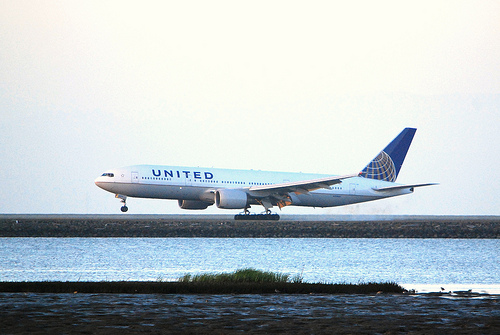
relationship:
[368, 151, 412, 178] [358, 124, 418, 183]
logo on tail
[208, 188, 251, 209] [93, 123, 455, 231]
engine on plane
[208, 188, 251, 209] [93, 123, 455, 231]
wing engine on plane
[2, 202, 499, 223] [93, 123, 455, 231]
runway under plane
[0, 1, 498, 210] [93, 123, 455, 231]
sky above plane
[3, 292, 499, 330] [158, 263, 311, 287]
space near grass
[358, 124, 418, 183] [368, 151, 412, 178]
tail has logo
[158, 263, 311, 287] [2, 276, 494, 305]
sea grass in riverbank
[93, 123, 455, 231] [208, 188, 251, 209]
plane has wing engine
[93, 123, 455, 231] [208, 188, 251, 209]
plane has engine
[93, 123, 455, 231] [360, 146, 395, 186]
plane has lines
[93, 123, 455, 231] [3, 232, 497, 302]
plane over water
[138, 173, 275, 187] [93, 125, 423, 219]
passenger windows on plane